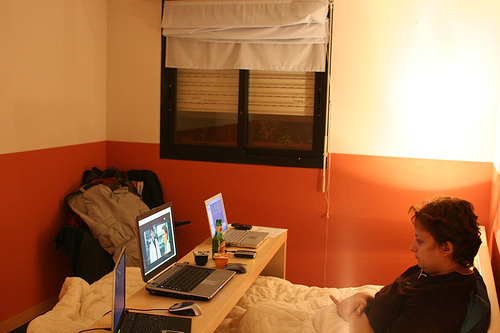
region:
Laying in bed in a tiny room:
[1, 0, 498, 332]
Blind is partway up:
[157, 1, 333, 172]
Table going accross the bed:
[71, 218, 291, 332]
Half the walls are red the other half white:
[2, 0, 499, 331]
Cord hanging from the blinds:
[321, 2, 333, 220]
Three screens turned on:
[106, 191, 234, 332]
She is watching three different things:
[108, 189, 498, 332]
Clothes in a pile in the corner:
[52, 162, 193, 283]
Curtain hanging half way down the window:
[156, 2, 333, 78]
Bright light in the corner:
[326, 0, 499, 194]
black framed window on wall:
[142, 1, 341, 174]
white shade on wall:
[157, 1, 337, 83]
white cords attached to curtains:
[319, 73, 336, 223]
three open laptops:
[107, 183, 290, 331]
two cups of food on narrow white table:
[187, 240, 234, 271]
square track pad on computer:
[200, 272, 222, 292]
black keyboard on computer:
[147, 260, 221, 299]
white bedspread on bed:
[20, 245, 385, 331]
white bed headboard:
[450, 206, 499, 331]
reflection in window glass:
[171, 102, 319, 158]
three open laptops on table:
[91, 189, 289, 331]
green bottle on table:
[208, 213, 227, 259]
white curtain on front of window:
[156, 29, 332, 87]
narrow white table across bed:
[81, 201, 292, 331]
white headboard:
[448, 215, 498, 331]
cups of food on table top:
[190, 243, 234, 270]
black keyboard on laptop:
[143, 259, 216, 298]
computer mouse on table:
[160, 295, 205, 321]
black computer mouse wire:
[94, 300, 167, 320]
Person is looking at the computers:
[311, 177, 496, 331]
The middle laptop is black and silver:
[116, 198, 261, 305]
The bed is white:
[241, 255, 364, 332]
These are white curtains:
[155, 3, 360, 102]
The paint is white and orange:
[361, 75, 431, 197]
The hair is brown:
[396, 191, 496, 273]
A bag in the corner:
[42, 140, 179, 301]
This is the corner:
[21, 15, 153, 150]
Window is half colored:
[151, 3, 362, 158]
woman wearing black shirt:
[405, 291, 440, 321]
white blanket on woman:
[293, 307, 318, 322]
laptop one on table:
[104, 258, 163, 325]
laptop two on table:
[140, 203, 202, 300]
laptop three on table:
[205, 196, 258, 248]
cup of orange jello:
[217, 253, 227, 266]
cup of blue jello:
[195, 250, 209, 262]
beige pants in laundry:
[95, 200, 110, 214]